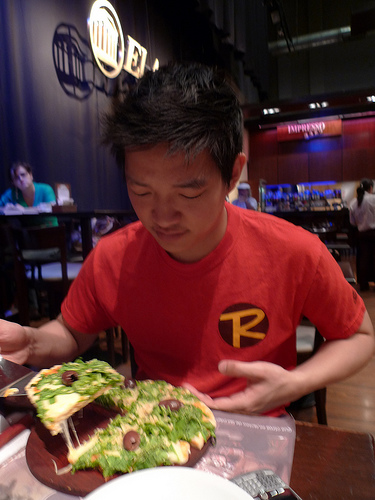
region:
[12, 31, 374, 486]
A person sitting in the pizza shop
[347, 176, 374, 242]
A person standing in the pizza shop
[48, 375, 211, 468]
Pizza kept in the wooden table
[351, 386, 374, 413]
Wooden type floor tiles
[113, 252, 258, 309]
A person wearing red color round neck t-shirt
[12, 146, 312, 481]
A person ready to eat pizza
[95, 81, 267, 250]
Head of the person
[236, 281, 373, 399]
Hand of the person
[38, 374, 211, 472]
Pizza kept in the plate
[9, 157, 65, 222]
A person sitting in the chair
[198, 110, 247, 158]
hair of a man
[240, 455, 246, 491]
;part of a phoone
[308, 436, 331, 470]
part of a table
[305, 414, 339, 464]
part of a table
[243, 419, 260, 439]
part of a cover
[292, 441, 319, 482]
part of a wood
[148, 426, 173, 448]
par of a food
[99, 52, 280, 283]
the head of a man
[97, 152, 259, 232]
the eyes of a man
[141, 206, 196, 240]
the nose of a man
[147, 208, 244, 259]
the mouth of a man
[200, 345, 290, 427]
the hand of a man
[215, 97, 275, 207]
the ear of a man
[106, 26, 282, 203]
the hair of a man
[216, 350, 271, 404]
the thumb of a man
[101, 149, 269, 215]
the eye brows of a man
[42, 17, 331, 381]
a man wearing a shirt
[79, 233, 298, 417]
the shirt is red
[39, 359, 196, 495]
pizza on wooden board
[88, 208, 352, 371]
shirt on the man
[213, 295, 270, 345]
graphic on the shirt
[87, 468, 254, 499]
plate on the table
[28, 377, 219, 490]
stone with food on it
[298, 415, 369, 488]
table with food and items on it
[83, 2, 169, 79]
graphic and lettering on wall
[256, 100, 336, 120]
light on the ceiling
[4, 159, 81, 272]
woman at table behind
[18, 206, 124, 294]
chair at the table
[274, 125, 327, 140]
lettering on plaque on wall